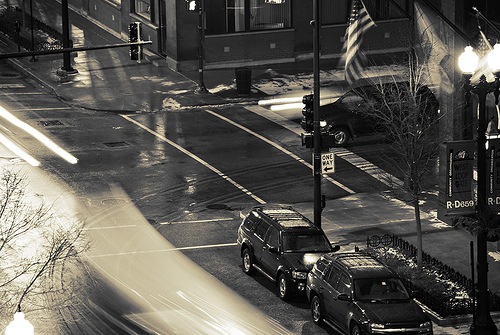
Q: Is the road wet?
A: Yes, the road is wet.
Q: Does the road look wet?
A: Yes, the road is wet.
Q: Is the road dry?
A: No, the road is wet.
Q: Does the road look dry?
A: No, the road is wet.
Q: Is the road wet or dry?
A: The road is wet.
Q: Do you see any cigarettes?
A: No, there are no cigarettes.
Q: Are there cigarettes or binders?
A: No, there are no cigarettes or binders.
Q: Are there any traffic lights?
A: Yes, there is a traffic light.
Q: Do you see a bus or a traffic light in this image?
A: Yes, there is a traffic light.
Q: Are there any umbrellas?
A: No, there are no umbrellas.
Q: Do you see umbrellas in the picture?
A: No, there are no umbrellas.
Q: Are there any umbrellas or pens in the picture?
A: No, there are no umbrellas or pens.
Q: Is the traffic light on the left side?
A: Yes, the traffic light is on the left of the image.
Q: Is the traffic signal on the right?
A: No, the traffic signal is on the left of the image.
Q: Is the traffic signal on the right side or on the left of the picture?
A: The traffic signal is on the left of the image.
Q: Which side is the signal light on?
A: The signal light is on the left of the image.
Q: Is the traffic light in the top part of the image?
A: Yes, the traffic light is in the top of the image.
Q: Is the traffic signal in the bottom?
A: No, the traffic signal is in the top of the image.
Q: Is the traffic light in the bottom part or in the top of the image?
A: The traffic light is in the top of the image.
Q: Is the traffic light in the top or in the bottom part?
A: The traffic light is in the top of the image.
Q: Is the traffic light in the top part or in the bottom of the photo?
A: The traffic light is in the top of the image.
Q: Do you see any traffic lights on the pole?
A: Yes, there is a traffic light on the pole.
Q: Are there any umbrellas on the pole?
A: No, there is a traffic light on the pole.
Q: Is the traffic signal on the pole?
A: Yes, the traffic signal is on the pole.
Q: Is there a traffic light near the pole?
A: Yes, there is a traffic light near the pole.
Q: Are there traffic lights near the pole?
A: Yes, there is a traffic light near the pole.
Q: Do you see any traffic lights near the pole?
A: Yes, there is a traffic light near the pole.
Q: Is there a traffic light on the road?
A: Yes, there is a traffic light on the road.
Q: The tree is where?
A: The tree is on the road.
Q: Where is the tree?
A: The tree is on the road.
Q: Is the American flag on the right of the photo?
A: Yes, the American flag is on the right of the image.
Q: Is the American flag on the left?
A: No, the American flag is on the right of the image.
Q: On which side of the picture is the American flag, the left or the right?
A: The American flag is on the right of the image.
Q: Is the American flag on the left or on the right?
A: The American flag is on the right of the image.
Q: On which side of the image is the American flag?
A: The American flag is on the right of the image.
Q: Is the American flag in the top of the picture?
A: Yes, the American flag is in the top of the image.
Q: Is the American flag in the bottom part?
A: No, the American flag is in the top of the image.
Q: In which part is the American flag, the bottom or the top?
A: The American flag is in the top of the image.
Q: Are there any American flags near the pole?
A: Yes, there is an American flag near the pole.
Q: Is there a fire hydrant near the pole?
A: No, there is an American flag near the pole.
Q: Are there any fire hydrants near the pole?
A: No, there is an American flag near the pole.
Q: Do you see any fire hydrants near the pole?
A: No, there is an American flag near the pole.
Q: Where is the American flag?
A: The American flag is on the road.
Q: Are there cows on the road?
A: No, there is an American flag on the road.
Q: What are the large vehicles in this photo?
A: The vehicles are cars.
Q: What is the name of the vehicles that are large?
A: The vehicles are cars.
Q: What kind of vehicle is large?
A: The vehicle is cars.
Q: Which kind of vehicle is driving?
A: The vehicle is cars.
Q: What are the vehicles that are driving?
A: The vehicles are cars.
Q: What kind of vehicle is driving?
A: The vehicle is cars.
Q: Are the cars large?
A: Yes, the cars are large.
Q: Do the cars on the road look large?
A: Yes, the cars are large.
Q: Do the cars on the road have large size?
A: Yes, the cars are large.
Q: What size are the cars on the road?
A: The cars are large.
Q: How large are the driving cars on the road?
A: The cars are large.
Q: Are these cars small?
A: No, the cars are large.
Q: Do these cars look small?
A: No, the cars are large.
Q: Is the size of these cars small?
A: No, the cars are large.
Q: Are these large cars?
A: Yes, these are large cars.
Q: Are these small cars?
A: No, these are large cars.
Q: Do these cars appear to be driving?
A: Yes, the cars are driving.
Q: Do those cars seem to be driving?
A: Yes, the cars are driving.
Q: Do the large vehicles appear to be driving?
A: Yes, the cars are driving.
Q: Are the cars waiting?
A: No, the cars are driving.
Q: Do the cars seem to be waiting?
A: No, the cars are driving.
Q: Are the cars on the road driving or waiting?
A: The cars are driving.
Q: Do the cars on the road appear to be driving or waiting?
A: The cars are driving.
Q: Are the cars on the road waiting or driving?
A: The cars are driving.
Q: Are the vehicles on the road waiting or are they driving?
A: The cars are driving.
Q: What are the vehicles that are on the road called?
A: The vehicles are cars.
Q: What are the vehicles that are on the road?
A: The vehicles are cars.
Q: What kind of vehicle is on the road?
A: The vehicles are cars.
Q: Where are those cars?
A: The cars are on the road.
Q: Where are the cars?
A: The cars are on the road.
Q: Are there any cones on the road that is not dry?
A: No, there are cars on the road.